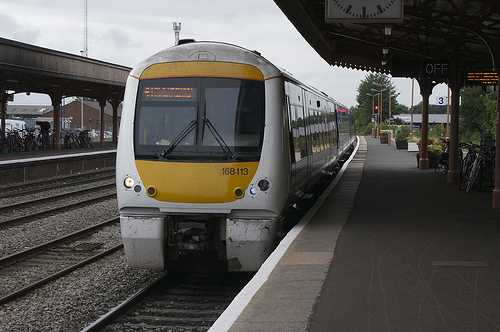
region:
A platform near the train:
[206, 134, 487, 330]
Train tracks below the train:
[81, 265, 241, 328]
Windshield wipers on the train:
[161, 115, 231, 155]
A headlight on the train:
[123, 175, 135, 187]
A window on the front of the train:
[136, 78, 256, 158]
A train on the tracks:
[116, 45, 352, 265]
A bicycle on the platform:
[459, 138, 486, 190]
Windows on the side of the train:
[285, 105, 340, 148]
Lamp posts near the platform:
[371, 80, 390, 135]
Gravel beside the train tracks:
[3, 244, 150, 330]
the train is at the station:
[103, 17, 318, 288]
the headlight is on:
[95, 157, 185, 209]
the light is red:
[358, 86, 382, 116]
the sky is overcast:
[53, 3, 324, 90]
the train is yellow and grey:
[79, 9, 320, 304]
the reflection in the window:
[286, 83, 369, 178]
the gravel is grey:
[16, 265, 130, 316]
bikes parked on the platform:
[0, 115, 108, 158]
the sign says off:
[402, 42, 465, 89]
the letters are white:
[408, 52, 456, 88]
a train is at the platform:
[104, 25, 361, 285]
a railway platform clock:
[319, 0, 411, 25]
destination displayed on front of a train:
[138, 82, 200, 102]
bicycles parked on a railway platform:
[3, 123, 99, 155]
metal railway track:
[67, 258, 252, 330]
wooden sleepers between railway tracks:
[94, 264, 259, 328]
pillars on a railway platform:
[408, 61, 465, 191]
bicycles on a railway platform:
[431, 124, 496, 201]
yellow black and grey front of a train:
[104, 37, 297, 279]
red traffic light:
[368, 92, 380, 142]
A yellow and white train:
[108, 36, 358, 267]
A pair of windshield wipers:
[158, 100, 238, 164]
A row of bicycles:
[430, 137, 495, 192]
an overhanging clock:
[323, 2, 407, 22]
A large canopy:
[273, 0, 498, 188]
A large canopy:
[0, 36, 132, 149]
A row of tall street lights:
[365, 77, 454, 142]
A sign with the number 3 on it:
[433, 93, 449, 106]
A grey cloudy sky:
[3, 3, 465, 105]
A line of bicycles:
[2, 123, 98, 152]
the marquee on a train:
[140, 79, 185, 104]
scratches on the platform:
[401, 255, 458, 311]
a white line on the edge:
[261, 237, 277, 282]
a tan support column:
[412, 85, 429, 171]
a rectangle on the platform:
[431, 247, 495, 274]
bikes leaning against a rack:
[460, 138, 482, 190]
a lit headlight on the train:
[118, 170, 143, 195]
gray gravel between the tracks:
[60, 281, 97, 313]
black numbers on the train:
[222, 160, 252, 182]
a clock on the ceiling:
[326, 0, 408, 27]